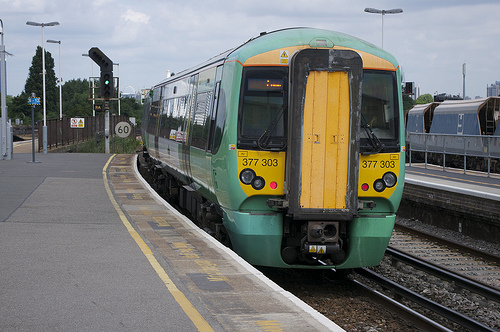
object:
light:
[86, 47, 131, 107]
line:
[102, 152, 339, 332]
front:
[227, 26, 405, 271]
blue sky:
[0, 0, 500, 98]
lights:
[250, 176, 265, 190]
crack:
[0, 217, 122, 227]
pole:
[31, 105, 36, 164]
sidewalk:
[0, 147, 348, 332]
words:
[102, 150, 351, 331]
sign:
[69, 117, 85, 128]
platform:
[0, 152, 349, 331]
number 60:
[118, 125, 130, 133]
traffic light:
[87, 46, 114, 98]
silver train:
[407, 93, 499, 154]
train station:
[285, 40, 457, 285]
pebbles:
[267, 269, 452, 332]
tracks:
[346, 268, 498, 332]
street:
[12, 138, 39, 154]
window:
[242, 71, 287, 141]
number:
[242, 157, 279, 167]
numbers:
[362, 160, 394, 169]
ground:
[257, 210, 500, 332]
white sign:
[115, 121, 133, 138]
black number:
[242, 157, 279, 166]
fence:
[38, 112, 128, 153]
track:
[342, 181, 500, 332]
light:
[363, 4, 403, 15]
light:
[25, 20, 61, 27]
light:
[239, 168, 257, 185]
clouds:
[0, 3, 499, 101]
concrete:
[0, 150, 345, 332]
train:
[140, 25, 406, 270]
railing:
[404, 133, 500, 181]